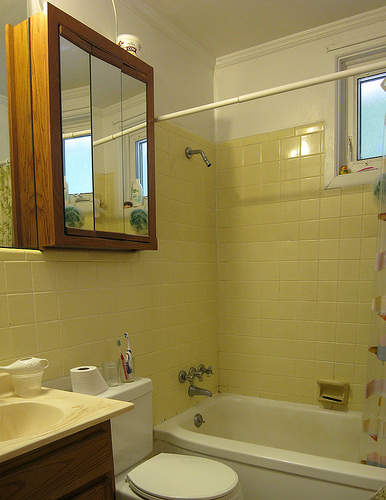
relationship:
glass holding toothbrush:
[117, 358, 137, 382] [122, 332, 132, 376]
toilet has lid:
[72, 373, 243, 500] [126, 450, 238, 499]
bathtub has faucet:
[154, 395, 384, 500] [178, 369, 197, 386]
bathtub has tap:
[154, 395, 384, 500] [189, 384, 212, 397]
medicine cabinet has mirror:
[4, 2, 159, 252] [56, 37, 94, 231]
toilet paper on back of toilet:
[70, 364, 108, 394] [72, 373, 243, 500]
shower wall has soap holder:
[214, 6, 382, 412] [316, 375, 351, 408]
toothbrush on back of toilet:
[122, 332, 132, 376] [72, 373, 243, 500]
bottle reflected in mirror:
[130, 179, 143, 206] [56, 37, 94, 231]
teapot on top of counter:
[2, 356, 49, 394] [0, 387, 134, 463]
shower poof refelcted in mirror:
[129, 207, 148, 234] [56, 37, 94, 231]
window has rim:
[358, 80, 385, 158] [325, 30, 385, 193]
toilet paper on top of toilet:
[70, 364, 108, 394] [72, 373, 243, 500]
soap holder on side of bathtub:
[316, 375, 351, 408] [154, 395, 384, 500]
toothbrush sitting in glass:
[122, 332, 132, 376] [117, 358, 137, 382]